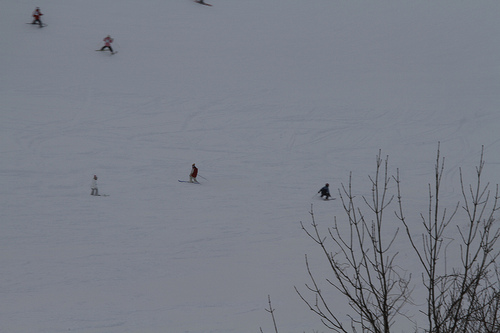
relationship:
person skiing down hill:
[25, 5, 47, 33] [0, 2, 499, 332]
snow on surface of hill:
[2, 2, 498, 332] [0, 2, 499, 332]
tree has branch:
[264, 141, 499, 332] [424, 137, 446, 331]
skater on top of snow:
[87, 172, 114, 199] [2, 2, 498, 332]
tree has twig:
[264, 141, 499, 332] [297, 219, 320, 247]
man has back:
[177, 159, 206, 186] [194, 165, 199, 179]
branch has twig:
[294, 205, 374, 324] [297, 219, 320, 247]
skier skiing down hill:
[313, 178, 338, 205] [0, 2, 499, 332]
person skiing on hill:
[25, 5, 47, 33] [0, 2, 499, 332]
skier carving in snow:
[313, 178, 338, 205] [2, 2, 498, 332]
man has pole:
[177, 159, 206, 186] [198, 171, 213, 187]